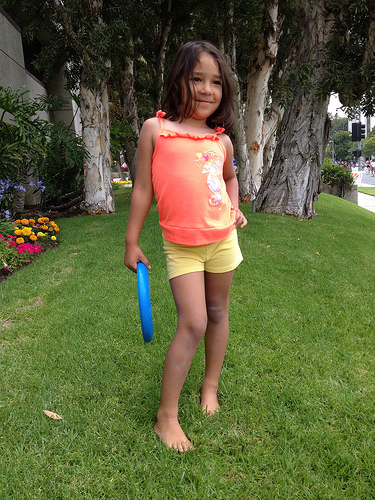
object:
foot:
[197, 384, 222, 416]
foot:
[154, 415, 194, 455]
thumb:
[138, 249, 152, 271]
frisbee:
[136, 260, 153, 342]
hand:
[124, 246, 151, 273]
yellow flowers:
[51, 236, 56, 241]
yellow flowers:
[121, 182, 122, 184]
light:
[351, 122, 367, 142]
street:
[337, 150, 374, 184]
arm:
[126, 117, 154, 246]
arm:
[223, 132, 240, 211]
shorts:
[161, 225, 244, 280]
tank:
[151, 118, 242, 246]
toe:
[181, 450, 183, 452]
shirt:
[152, 110, 240, 245]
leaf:
[43, 410, 62, 420]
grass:
[324, 460, 341, 487]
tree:
[48, 1, 123, 216]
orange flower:
[54, 227, 59, 231]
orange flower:
[43, 225, 48, 229]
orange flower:
[44, 218, 49, 222]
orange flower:
[29, 218, 35, 223]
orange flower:
[21, 218, 29, 224]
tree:
[250, 0, 345, 220]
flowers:
[51, 236, 56, 240]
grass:
[3, 480, 19, 496]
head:
[160, 37, 237, 121]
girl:
[123, 39, 249, 454]